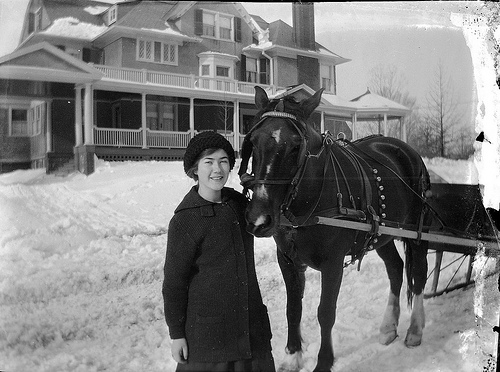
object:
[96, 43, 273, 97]
balcony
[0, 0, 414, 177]
house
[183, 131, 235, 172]
knit beanie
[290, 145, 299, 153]
eye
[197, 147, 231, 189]
head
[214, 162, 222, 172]
nose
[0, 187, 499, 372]
ground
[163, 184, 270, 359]
sweater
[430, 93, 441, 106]
branches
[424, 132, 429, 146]
branches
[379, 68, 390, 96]
branches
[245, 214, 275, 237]
nose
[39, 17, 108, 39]
snow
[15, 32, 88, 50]
roof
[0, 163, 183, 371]
snow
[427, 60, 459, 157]
tree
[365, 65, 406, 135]
tree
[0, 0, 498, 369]
photograph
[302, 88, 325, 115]
ear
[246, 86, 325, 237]
head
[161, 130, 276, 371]
girl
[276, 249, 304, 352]
legs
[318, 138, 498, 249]
sleigh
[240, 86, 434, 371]
horse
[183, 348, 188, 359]
thumb